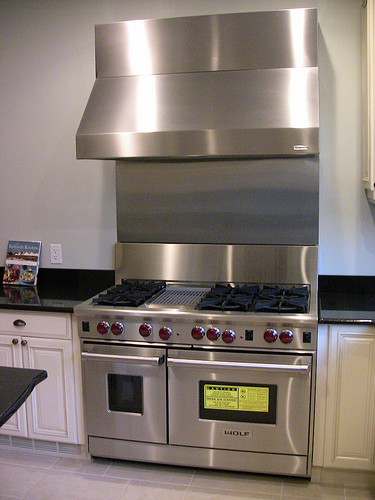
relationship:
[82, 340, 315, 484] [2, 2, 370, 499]
oven in kitchen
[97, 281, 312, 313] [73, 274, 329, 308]
burners on stove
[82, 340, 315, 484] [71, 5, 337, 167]
oven has hood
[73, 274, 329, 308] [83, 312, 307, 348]
stove has dials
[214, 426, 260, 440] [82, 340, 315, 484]
logo on oven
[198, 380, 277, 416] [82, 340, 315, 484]
sticker on oven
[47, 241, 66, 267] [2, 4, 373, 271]
outlet on wall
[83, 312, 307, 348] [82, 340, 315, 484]
dials on oven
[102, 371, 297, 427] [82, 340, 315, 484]
glass on oven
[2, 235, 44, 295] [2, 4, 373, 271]
book against wall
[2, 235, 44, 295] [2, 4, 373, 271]
book leaning against wall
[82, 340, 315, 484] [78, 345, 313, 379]
oven has handle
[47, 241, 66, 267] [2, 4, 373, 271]
outlet in wall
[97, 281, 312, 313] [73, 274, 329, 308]
burners on top of stove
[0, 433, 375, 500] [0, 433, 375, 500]
floor on floor